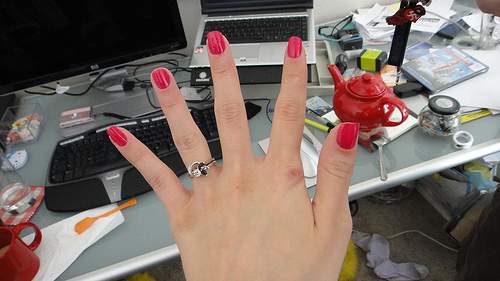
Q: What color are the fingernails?
A: Pink.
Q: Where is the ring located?
A: Ring finger.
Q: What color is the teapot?
A: Red.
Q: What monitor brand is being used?
A: HP.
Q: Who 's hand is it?
A: A woman's.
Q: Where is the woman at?
A: Office.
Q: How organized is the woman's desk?
A: Not very organized.